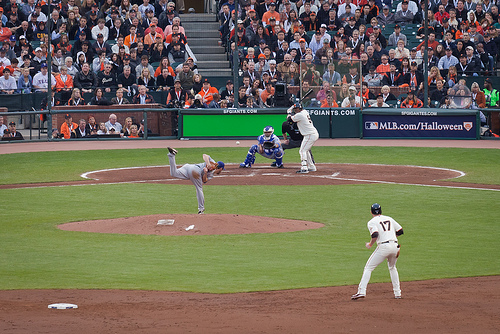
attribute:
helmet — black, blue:
[292, 102, 302, 111]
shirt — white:
[289, 108, 317, 137]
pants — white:
[298, 134, 318, 166]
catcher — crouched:
[241, 125, 285, 169]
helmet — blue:
[264, 126, 275, 133]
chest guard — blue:
[258, 136, 273, 153]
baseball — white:
[235, 139, 240, 145]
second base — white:
[46, 302, 78, 311]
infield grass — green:
[0, 181, 499, 291]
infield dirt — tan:
[0, 160, 498, 333]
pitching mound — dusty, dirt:
[58, 212, 325, 238]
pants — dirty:
[165, 155, 208, 210]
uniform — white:
[290, 111, 321, 174]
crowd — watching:
[0, 0, 500, 108]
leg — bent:
[165, 147, 187, 179]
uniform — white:
[354, 214, 406, 296]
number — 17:
[379, 220, 391, 233]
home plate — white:
[262, 171, 279, 176]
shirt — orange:
[264, 11, 282, 23]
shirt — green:
[485, 89, 500, 107]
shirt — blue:
[436, 55, 458, 68]